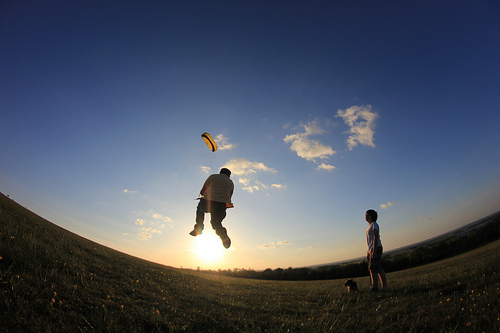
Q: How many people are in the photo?
A: Two.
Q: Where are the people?
A: In a field.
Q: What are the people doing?
A: Flying a kite.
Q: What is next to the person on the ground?
A: A dog.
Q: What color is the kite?
A: Yellow.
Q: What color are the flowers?
A: Yellow.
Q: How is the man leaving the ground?
A: The kite.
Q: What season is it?
A: Summer.